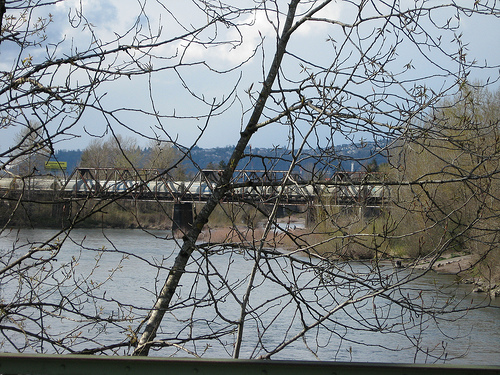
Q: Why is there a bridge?
A: Cross the water.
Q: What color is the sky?
A: Blue.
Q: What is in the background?
A: Trees.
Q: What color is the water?
A: Brown.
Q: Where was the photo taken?
A: River.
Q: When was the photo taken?
A: Afternoon.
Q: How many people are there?
A: 0.